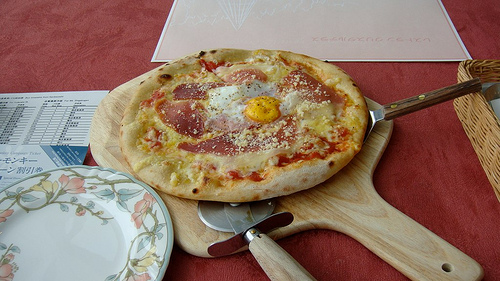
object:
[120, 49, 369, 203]
pizza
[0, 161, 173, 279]
plate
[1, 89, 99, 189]
menu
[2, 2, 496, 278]
table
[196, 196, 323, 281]
pizza cutter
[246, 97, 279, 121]
egg yolk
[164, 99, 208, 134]
ham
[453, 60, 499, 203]
basket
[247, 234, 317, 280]
handle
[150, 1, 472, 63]
poster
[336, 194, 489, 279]
handle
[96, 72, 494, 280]
pizza board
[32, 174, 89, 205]
flowers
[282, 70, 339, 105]
meat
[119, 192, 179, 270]
floral pattern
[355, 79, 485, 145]
pizza server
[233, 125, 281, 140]
cheese